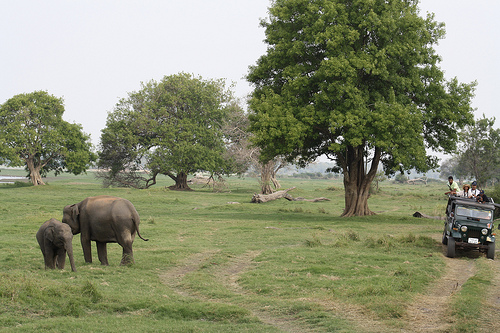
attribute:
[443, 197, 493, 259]
truck — top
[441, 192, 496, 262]
vehicle — dark, green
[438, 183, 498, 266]
jeep — black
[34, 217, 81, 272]
elephant — baby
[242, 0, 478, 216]
tree — large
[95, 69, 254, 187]
tree — large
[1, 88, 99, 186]
tree — large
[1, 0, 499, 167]
sky — clear, bright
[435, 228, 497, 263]
wheels — black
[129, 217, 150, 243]
tail — curved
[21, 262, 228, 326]
grass — patch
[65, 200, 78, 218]
ear — elephant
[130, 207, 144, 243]
tail — elephant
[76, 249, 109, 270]
legs — elephant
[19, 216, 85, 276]
elephant — infant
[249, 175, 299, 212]
trunk — tree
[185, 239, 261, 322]
marks — rut